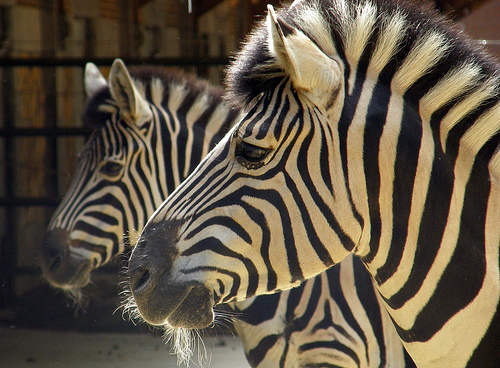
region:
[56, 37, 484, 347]
the zebras are stripes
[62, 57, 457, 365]
zebras are black and white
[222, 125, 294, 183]
zebra's eye is black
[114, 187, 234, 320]
zebra's nose is brown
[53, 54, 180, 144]
zebra has two ears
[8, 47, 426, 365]
zebras are looking on it's right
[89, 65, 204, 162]
zebra's ear is white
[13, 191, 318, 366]
the zebras have nose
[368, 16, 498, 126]
the zebra has mane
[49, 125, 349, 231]
the zebras have eyes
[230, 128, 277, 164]
The left eye of a zebra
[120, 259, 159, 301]
The nose of a zebra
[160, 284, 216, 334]
A zebra's closed mouth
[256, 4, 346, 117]
A zebra's left ear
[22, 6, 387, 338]
Two zebra's next to each other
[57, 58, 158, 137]
A pair of ears from a zebra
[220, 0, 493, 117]
Hair on a zebra's head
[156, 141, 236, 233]
Black and white stripes on the zebra's head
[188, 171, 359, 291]
A colorful pattern of black and white stripes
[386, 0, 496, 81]
Finely trimmed hair on a zebra's head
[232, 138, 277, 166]
the eye of the zebra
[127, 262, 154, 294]
the nostril of the zebra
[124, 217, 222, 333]
the snout of the zebra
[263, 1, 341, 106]
the ear of the zebra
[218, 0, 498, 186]
the mane of the zebra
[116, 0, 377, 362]
the head of the zebra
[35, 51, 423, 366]
a zebra in the background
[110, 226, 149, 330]
the nose hairs of a zebra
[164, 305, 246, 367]
the whiskers of a zebra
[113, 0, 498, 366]
a zebra in the foreground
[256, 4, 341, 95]
The ear of the zebra.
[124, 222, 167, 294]
The nose of the zebra.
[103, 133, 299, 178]
The eyes of the zebras.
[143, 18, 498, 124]
The black and white mane of the zebras.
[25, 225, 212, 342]
The mouths of both of the zebras.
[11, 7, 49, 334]
The window of the building.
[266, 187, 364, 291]
The jaw line of the zebra.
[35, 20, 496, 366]
Two zebras facing ahead.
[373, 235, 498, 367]
The neck of one of the zebras.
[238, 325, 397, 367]
The body of the zebra.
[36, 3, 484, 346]
a pair of zebras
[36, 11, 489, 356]
two black and white animals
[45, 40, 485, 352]
two wild animals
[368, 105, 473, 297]
black and white striped fur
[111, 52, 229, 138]
an animal version of mohawk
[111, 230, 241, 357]
a bunch of whiskers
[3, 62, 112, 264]
a wall with square pattern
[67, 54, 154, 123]
a pair of furry ears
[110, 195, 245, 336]
a soft black nose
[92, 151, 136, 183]
a large black eye